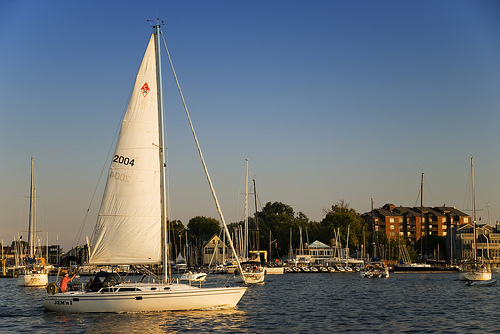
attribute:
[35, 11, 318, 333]
boat — sail, motor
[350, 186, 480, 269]
building — multi-story, brick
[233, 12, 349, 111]
sky — blue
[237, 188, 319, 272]
tree — green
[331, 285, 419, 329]
water — body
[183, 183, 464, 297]
town — seaside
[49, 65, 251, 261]
sail — white, boat